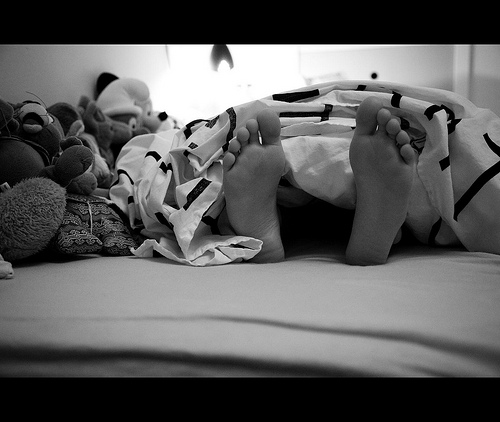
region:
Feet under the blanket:
[218, 97, 415, 265]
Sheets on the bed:
[2, 251, 499, 377]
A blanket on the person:
[113, 81, 499, 263]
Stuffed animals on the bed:
[1, 77, 166, 255]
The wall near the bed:
[0, 45, 499, 115]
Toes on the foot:
[220, 109, 282, 167]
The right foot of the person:
[221, 111, 286, 261]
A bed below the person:
[1, 254, 499, 376]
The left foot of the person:
[350, 96, 412, 262]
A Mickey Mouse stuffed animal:
[123, 82, 165, 129]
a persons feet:
[224, 103, 418, 266]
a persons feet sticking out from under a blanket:
[125, 92, 499, 262]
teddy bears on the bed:
[6, 95, 143, 258]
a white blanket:
[134, 93, 499, 294]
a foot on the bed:
[224, 108, 285, 263]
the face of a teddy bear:
[139, 105, 176, 132]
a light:
[156, 52, 329, 112]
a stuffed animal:
[18, 98, 90, 182]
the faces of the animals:
[79, 95, 177, 138]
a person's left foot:
[346, 100, 410, 264]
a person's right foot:
[216, 105, 296, 262]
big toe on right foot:
[258, 108, 281, 141]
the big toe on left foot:
[358, 94, 378, 136]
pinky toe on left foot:
[401, 142, 419, 165]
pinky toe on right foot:
[219, 153, 239, 169]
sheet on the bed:
[151, 144, 222, 254]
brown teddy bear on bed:
[0, 103, 94, 183]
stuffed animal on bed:
[84, 96, 130, 161]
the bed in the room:
[0, 262, 499, 376]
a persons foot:
[221, 139, 290, 258]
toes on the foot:
[360, 99, 398, 135]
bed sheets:
[113, 260, 366, 340]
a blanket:
[287, 90, 343, 137]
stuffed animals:
[84, 95, 154, 130]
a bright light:
[162, 64, 215, 105]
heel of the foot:
[342, 244, 368, 266]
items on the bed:
[14, 182, 127, 252]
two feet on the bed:
[223, 102, 420, 256]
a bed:
[121, 269, 364, 334]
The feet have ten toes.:
[213, 97, 415, 267]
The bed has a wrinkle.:
[276, 274, 398, 352]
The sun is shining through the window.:
[171, 51, 240, 105]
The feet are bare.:
[211, 96, 416, 261]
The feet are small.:
[225, 96, 411, 263]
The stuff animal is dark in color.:
[57, 137, 98, 192]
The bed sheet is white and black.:
[126, 150, 246, 255]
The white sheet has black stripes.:
[116, 141, 237, 257]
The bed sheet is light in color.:
[121, 262, 222, 328]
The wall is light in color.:
[22, 51, 83, 88]